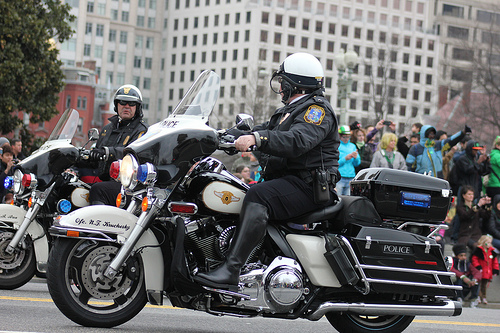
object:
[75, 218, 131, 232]
name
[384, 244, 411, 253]
lettering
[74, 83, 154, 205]
man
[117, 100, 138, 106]
sunglasses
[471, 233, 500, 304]
child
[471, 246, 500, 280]
coat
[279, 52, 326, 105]
head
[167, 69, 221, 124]
windshield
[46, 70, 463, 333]
bike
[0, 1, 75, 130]
leaves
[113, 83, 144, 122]
helmet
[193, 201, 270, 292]
boot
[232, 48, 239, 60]
windows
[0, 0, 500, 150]
building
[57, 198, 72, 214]
blue light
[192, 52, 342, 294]
man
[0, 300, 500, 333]
street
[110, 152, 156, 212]
lights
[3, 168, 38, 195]
lights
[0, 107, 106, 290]
motorcycle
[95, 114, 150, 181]
jacket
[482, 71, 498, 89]
limbs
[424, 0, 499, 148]
tree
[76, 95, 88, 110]
windows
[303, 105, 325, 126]
logo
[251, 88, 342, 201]
jacket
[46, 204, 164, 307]
fender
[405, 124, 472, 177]
man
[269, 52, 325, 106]
helmet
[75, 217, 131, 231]
script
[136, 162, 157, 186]
light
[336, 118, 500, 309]
crowd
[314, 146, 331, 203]
walkietalkie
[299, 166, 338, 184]
belt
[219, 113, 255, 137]
mirror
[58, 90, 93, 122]
wall